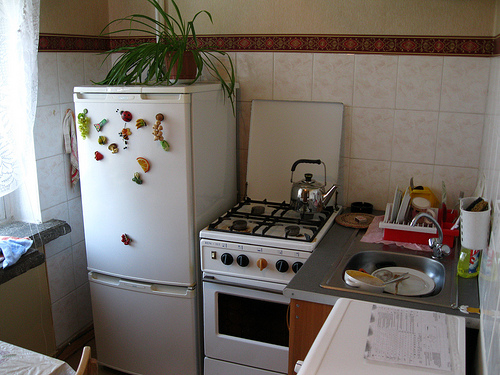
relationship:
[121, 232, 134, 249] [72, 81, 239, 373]
magnet on refrigerator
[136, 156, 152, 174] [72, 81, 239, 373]
magnet on refrigerator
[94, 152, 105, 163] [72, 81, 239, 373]
magnet on refrigerator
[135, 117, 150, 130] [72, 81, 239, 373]
magnet on refrigerator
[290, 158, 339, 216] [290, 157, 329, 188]
teakettle has handle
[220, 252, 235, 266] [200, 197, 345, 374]
knob on stove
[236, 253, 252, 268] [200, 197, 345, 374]
knob on stove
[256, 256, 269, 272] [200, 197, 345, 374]
knob on stove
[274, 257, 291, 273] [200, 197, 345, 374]
knob on stove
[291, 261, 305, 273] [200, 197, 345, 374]
knob on stove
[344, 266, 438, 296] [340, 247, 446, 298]
dishes in sink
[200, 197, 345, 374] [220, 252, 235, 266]
stove with knob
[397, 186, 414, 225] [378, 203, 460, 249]
dish in holder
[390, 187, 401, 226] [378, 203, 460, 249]
dish in holder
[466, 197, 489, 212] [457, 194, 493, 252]
sponge in holder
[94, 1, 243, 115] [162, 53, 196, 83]
plant in pot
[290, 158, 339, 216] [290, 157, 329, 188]
kettle has handle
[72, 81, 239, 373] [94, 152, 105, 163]
refrigerator has magnet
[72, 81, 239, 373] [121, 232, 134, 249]
refrigerator has magnet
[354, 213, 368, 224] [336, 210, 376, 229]
matches on mat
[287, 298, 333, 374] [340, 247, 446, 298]
cabinet under sink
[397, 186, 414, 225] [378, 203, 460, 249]
dish on strainer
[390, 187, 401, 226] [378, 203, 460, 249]
dish on strainer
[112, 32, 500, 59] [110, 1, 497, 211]
border on wall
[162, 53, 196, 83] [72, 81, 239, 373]
pot top of fridge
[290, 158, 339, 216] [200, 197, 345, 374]
kettle on stove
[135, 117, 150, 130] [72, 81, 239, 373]
magnet on fridge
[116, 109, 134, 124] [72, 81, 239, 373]
magnet on fridge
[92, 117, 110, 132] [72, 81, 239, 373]
magnet on fridge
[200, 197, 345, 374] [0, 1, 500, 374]
stove in kitchen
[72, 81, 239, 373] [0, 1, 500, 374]
refrigerator in kitchen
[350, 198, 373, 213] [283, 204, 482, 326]
ashtray on counter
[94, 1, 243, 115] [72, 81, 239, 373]
plant top of refrigerator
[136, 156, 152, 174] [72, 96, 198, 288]
magnet on door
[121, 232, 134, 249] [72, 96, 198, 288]
magnet on door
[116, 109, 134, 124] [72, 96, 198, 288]
magnet on door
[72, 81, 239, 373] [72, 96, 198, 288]
refrigerator has door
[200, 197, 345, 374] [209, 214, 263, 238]
stove with burner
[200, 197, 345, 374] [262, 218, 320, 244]
stove with burner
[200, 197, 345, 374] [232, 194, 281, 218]
stove with burner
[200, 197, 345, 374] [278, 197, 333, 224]
stove with burner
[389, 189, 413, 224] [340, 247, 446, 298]
dishes next to sink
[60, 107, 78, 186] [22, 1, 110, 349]
towel on wall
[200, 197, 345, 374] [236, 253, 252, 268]
stove with knob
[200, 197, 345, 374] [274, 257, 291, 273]
stove with knob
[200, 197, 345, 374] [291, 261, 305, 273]
stove with knob